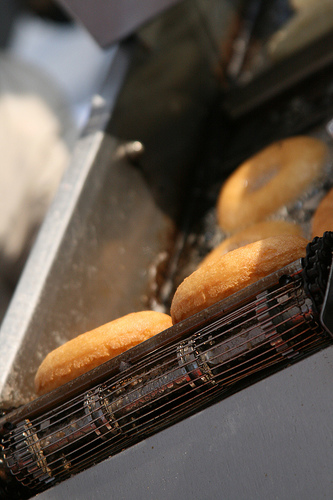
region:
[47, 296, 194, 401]
a food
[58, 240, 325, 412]
a food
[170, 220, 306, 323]
crispy golden fried doughnut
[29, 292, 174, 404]
crispy golden fried doughnut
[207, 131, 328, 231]
doughnut frying in oil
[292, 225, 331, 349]
rotating metal gear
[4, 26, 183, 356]
blurry silver wall of a doughnut fryer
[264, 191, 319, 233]
bubbling hot fryer oil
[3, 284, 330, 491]
spokes that carry doughnuts through hot oil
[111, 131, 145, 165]
blurry bolt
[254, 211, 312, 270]
shadow on a doughnut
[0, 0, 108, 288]
undescript blurriness in the background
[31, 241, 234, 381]
a food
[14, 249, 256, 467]
a food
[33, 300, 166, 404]
a newly cooked donut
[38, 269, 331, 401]
two newly cooked donuts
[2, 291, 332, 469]
donuts going down a conveyer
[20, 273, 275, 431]
un-glazed donuts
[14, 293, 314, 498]
metal conveyor belt moving donuts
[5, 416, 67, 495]
A gear turning the conveyor belt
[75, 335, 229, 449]
two gears turning the conveyor belt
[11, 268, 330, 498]
machine turning out cooked donuts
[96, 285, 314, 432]
metal wires built into the machine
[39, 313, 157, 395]
crusted light baked donut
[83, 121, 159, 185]
a stud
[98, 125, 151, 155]
a stud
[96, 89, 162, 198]
a stud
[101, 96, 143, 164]
a stud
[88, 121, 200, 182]
a stud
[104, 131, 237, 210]
a stud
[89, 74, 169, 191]
a stud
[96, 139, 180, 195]
a stud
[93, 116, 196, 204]
a stud